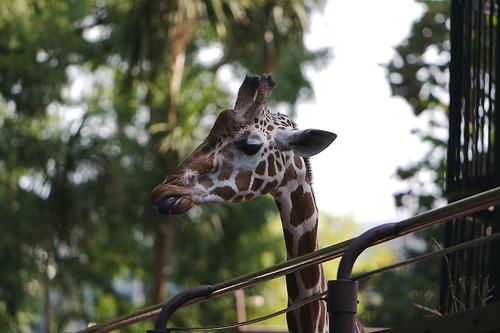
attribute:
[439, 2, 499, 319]
iron cage — black, behind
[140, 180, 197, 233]
tongue — black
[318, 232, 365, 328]
pole — metal, black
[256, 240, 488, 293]
fence — metal, black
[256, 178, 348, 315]
neck — long, skinny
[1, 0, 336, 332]
trees — tall, green, growing, behind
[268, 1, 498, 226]
skies — cloudy, white, over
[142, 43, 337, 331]
giraffe — sticking out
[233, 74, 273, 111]
horns — brown, black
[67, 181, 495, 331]
metal fence — silver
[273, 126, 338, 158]
ear — sticking over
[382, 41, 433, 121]
leaves — small, green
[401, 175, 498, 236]
rail — grey, metal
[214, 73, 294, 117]
horns — black, brown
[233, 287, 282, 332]
wood piece — small, yellow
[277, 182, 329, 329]
giraffe neck — long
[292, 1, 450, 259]
sky — bright, gray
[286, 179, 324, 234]
spots — white, brown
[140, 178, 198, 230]
black tongue — hanging out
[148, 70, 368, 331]
giraffe — looking over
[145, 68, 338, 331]
giraffe — black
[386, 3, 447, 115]
leaves — green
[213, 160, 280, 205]
spots — brown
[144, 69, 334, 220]
head — over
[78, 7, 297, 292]
palm tree — growing, inside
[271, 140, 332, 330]
neck — long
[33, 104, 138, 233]
leaf — green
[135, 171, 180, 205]
nose — brown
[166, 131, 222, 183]
strip — brown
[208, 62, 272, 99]
horn — brown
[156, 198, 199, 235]
tongue — black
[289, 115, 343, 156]
ear — white